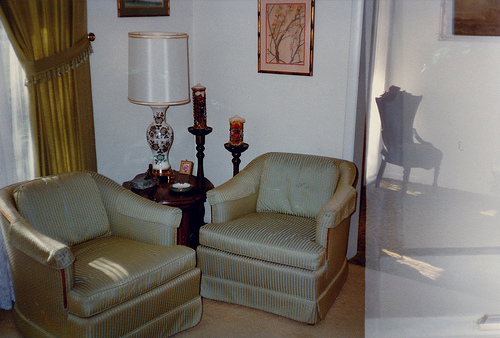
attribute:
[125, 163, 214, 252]
table — wood, brown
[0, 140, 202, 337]
chair — tan, upholstered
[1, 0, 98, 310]
curtains — golden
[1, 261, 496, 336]
carpeting — brown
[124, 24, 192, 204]
lamp — decorative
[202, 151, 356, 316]
chair — upholstered, tan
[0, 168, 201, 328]
chair — older, upholstered, tan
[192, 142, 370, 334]
chair — tan, upholstered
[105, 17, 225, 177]
lampshade — white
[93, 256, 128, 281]
sunlight — tan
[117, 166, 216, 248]
table — round, brown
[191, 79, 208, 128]
candle — fancy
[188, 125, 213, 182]
stand — fancy, wood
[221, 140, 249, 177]
stand — fancy, wood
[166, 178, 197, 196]
ashtray — empty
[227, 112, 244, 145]
candle — fancy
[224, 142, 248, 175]
stand — brown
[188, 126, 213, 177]
stand — brown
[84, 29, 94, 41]
fastener — decorative, gold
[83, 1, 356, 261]
wall — white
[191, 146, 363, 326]
chair — older, upholstered, tan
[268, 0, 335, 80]
picture — brown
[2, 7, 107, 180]
curtain — white , sheer , long 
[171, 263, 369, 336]
carpet — brown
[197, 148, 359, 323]
seat — gray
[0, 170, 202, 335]
seat — gray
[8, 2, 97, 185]
drapes — gold 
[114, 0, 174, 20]
art — framed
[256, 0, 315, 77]
frame — pink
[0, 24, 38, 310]
sheer — white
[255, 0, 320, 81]
frame — gold